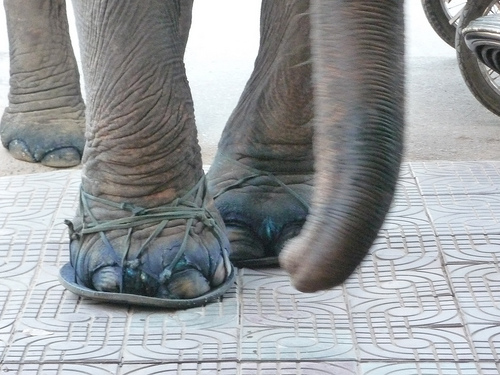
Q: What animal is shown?
A: An elephant.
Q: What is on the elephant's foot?
A: String.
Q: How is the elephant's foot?
A: Bound.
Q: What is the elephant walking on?
A: Tile.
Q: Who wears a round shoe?
A: An elephant.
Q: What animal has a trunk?
A: The elephant.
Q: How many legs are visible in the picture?
A: Three.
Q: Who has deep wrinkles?
A: An elephant.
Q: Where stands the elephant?
A: On cement.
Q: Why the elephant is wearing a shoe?
A: Because is injured.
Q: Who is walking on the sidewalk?
A: An elephant.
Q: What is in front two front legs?
A: A trunk.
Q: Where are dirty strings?
A: Over a foot.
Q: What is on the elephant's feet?
A: Sandals.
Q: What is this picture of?
A: Elephant feet and trunk.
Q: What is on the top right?
A: Bike wheels.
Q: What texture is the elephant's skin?
A: Wrinkly.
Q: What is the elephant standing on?
A: Decorative tiles.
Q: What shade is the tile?
A: Light.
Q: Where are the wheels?
A: Top right.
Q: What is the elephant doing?
A: Standing.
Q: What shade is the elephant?
A: Brown and gray.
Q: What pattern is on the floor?
A: Geometric.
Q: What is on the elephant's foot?
A: Shoe.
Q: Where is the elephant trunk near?
A: Elephant feet.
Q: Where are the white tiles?
A: On the floor.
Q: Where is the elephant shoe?
A: On the elephant's foot.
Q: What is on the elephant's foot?
A: A shoe.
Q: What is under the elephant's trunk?
A: Tiles.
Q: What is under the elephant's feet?
A: Tiles.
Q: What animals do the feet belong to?
A: An elephant.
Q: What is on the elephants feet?
A: Sandals.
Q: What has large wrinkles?
A: Elephant.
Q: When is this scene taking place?
A: Daytime.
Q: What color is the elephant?
A: Brown and grey.